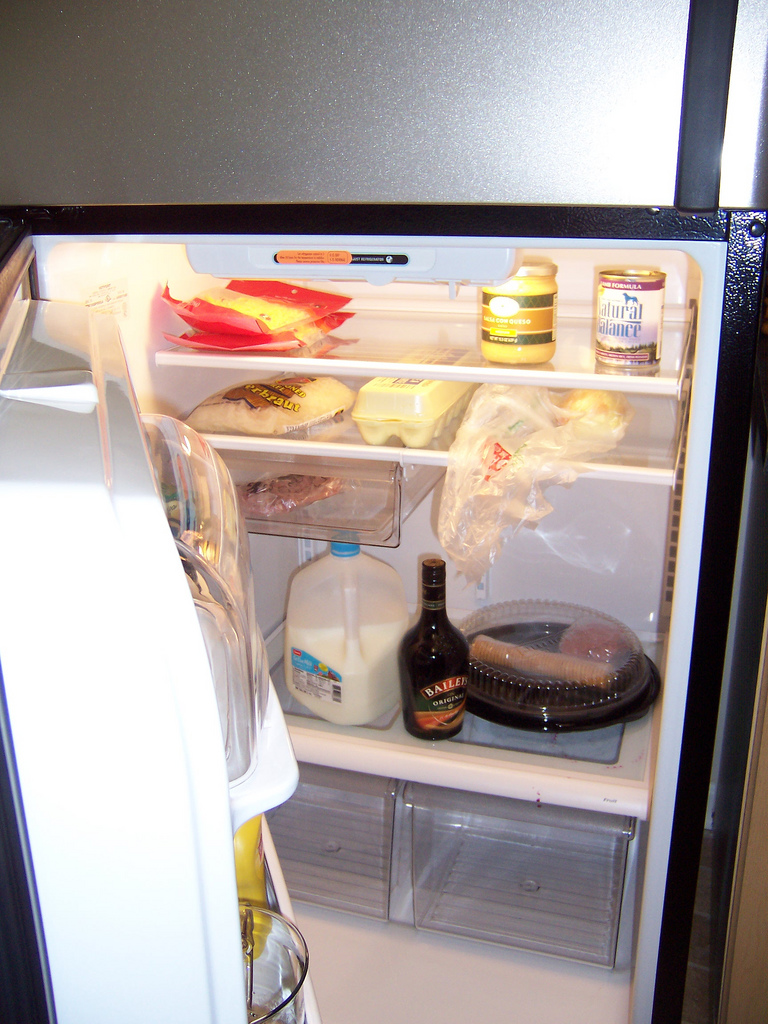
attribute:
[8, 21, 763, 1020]
door — open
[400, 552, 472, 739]
black bottle — Baileys, with black cap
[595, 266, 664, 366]
purple/white can — dog food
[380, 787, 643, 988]
bin — plastic, clear, empty